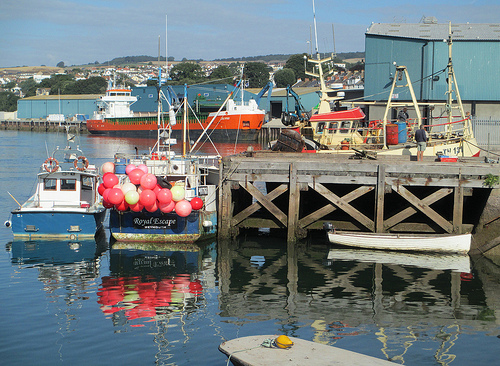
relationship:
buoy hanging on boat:
[3, 218, 12, 230] [5, 157, 106, 238]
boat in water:
[328, 227, 472, 253] [0, 129, 500, 365]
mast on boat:
[446, 22, 455, 138] [268, 22, 481, 161]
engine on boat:
[195, 95, 224, 115] [86, 73, 265, 140]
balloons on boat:
[98, 161, 204, 217] [108, 150, 220, 245]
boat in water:
[5, 157, 106, 238] [0, 129, 500, 365]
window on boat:
[61, 178, 75, 191] [5, 157, 106, 238]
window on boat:
[43, 177, 58, 192] [5, 157, 106, 238]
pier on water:
[219, 150, 499, 240] [0, 129, 500, 365]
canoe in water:
[328, 227, 472, 253] [0, 129, 500, 365]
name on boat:
[133, 217, 178, 229] [108, 150, 220, 245]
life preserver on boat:
[44, 154, 89, 172] [5, 157, 106, 238]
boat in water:
[86, 73, 265, 140] [0, 129, 500, 365]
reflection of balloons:
[99, 270, 205, 326] [98, 161, 204, 217]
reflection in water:
[99, 270, 205, 326] [0, 129, 500, 365]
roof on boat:
[298, 106, 366, 121] [268, 22, 481, 161]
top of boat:
[14, 165, 105, 211] [5, 157, 106, 238]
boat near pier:
[328, 227, 472, 253] [217, 150, 500, 256]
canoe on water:
[328, 227, 472, 253] [0, 129, 500, 365]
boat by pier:
[268, 22, 481, 161] [219, 150, 499, 240]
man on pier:
[414, 124, 428, 161] [219, 150, 499, 240]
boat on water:
[86, 73, 265, 140] [0, 129, 500, 365]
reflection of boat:
[12, 238, 105, 303] [5, 157, 106, 238]